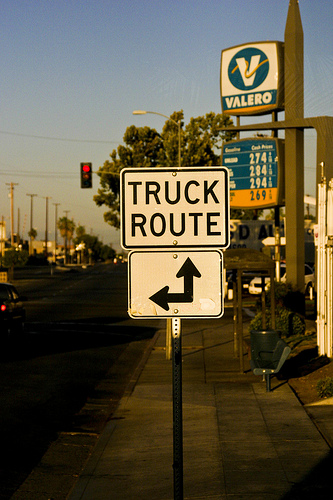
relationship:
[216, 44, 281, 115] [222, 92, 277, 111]
sign has word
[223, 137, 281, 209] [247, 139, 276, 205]
sign has gas prices